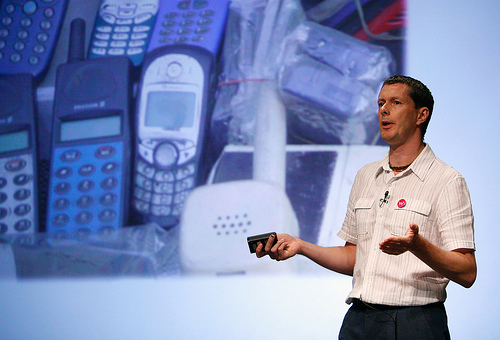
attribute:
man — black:
[255, 71, 477, 338]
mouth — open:
[379, 118, 396, 128]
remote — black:
[243, 220, 287, 250]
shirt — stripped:
[341, 149, 470, 300]